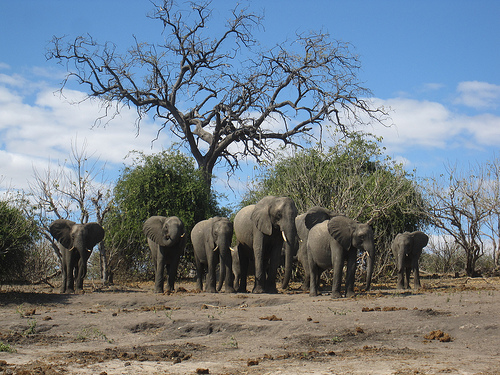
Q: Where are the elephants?
A: Dirt walking.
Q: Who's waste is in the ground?
A: Elephant.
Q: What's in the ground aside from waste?
A: Holes.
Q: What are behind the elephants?
A: Tree.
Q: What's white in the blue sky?
A: Clouds.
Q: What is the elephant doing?
A: Standing in the field.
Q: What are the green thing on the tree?
A: Leaves.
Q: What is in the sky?
A: Clouds.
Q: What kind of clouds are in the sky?
A: White fluffy clouds.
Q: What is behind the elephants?
A: Trees.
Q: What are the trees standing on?
A: Dirt.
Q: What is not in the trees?
A: Leaves.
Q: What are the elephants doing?
A: Walking.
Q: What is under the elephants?
A: Bare ground sand.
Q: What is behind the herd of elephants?
A: Trees.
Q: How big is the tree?
A: Very tall.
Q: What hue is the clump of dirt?
A: Brown.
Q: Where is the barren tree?
A: Behind the elephants.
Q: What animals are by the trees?
A: Elephants.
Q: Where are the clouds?
A: In the sky.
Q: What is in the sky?
A: Clouds.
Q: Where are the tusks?
A: On the elephants.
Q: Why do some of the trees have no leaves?
A: They are dead.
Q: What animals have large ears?
A: The elephants.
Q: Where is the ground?
A: Under the elephants.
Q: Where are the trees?
A: Behind the elephants.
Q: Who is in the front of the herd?
A: An elephant.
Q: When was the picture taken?
A: Daytime.